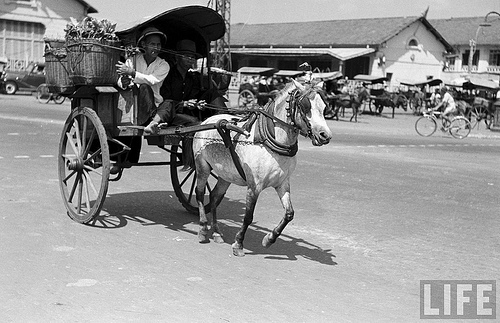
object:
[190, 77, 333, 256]
horse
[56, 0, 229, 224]
carriage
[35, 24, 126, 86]
basket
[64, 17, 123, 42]
plants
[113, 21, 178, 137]
man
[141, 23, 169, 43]
hat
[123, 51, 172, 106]
white shirt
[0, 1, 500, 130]
carriages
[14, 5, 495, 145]
background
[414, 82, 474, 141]
person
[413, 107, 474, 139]
bicycle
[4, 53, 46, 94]
car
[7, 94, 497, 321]
road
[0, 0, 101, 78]
building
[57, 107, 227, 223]
wheels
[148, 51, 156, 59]
cigarette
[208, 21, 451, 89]
building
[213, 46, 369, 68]
awning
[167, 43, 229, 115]
man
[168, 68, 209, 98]
shirt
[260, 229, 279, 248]
hoof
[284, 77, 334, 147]
head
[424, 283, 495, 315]
life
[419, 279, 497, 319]
letters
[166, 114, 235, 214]
wheel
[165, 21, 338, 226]
right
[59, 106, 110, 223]
left wheel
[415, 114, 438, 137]
front wheel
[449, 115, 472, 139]
back wheel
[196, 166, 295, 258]
legs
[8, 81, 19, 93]
tire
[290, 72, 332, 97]
ears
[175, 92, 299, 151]
harness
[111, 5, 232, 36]
roof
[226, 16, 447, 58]
roof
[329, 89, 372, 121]
horse